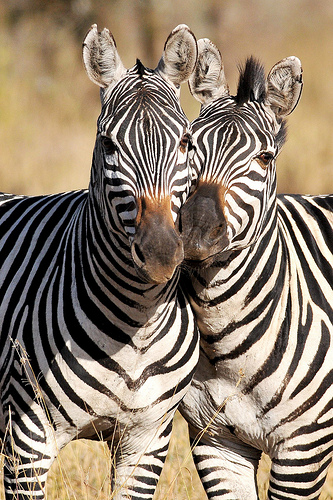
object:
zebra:
[0, 21, 200, 498]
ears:
[81, 24, 116, 84]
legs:
[0, 445, 60, 500]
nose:
[132, 221, 184, 277]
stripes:
[1, 68, 333, 497]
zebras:
[0, 23, 332, 496]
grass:
[64, 447, 183, 498]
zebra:
[183, 32, 333, 498]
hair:
[236, 57, 266, 105]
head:
[178, 88, 278, 264]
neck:
[88, 235, 185, 328]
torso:
[1, 315, 198, 453]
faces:
[94, 99, 188, 280]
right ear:
[162, 26, 199, 84]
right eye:
[179, 132, 190, 147]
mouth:
[134, 242, 187, 285]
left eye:
[97, 127, 118, 155]